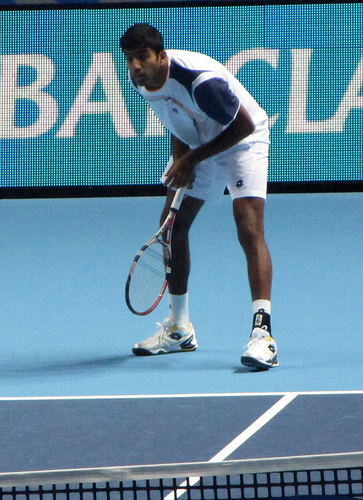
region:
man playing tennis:
[115, 19, 281, 373]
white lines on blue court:
[2, 387, 362, 499]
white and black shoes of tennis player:
[129, 325, 278, 368]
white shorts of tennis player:
[159, 152, 268, 196]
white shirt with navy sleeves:
[135, 53, 269, 150]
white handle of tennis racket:
[165, 179, 190, 207]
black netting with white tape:
[1, 452, 360, 499]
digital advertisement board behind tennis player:
[3, 7, 362, 184]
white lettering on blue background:
[4, 40, 361, 158]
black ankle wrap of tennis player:
[253, 308, 273, 330]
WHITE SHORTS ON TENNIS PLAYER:
[177, 122, 278, 208]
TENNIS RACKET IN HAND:
[129, 231, 172, 332]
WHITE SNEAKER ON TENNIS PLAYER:
[230, 322, 297, 387]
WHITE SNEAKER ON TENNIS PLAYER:
[132, 338, 199, 368]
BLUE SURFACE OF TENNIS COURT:
[19, 356, 285, 483]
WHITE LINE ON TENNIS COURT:
[195, 385, 295, 476]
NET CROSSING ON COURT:
[53, 432, 335, 499]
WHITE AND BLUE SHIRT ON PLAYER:
[154, 58, 251, 161]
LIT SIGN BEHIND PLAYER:
[26, 34, 354, 201]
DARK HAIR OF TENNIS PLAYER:
[120, 14, 183, 55]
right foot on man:
[125, 316, 213, 355]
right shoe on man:
[100, 295, 215, 373]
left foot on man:
[230, 296, 281, 388]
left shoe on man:
[219, 316, 300, 400]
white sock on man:
[151, 270, 202, 333]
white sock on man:
[240, 298, 290, 339]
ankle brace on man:
[230, 308, 289, 344]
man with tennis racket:
[151, 163, 209, 319]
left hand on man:
[143, 144, 196, 183]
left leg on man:
[229, 171, 280, 292]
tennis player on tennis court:
[104, 21, 290, 371]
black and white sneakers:
[118, 319, 287, 373]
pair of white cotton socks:
[161, 287, 275, 330]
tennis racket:
[120, 172, 192, 320]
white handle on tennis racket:
[169, 180, 189, 216]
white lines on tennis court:
[1, 387, 361, 496]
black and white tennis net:
[1, 448, 361, 498]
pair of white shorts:
[157, 114, 273, 202]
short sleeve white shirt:
[126, 46, 275, 155]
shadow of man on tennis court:
[2, 339, 258, 392]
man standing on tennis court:
[95, 15, 295, 375]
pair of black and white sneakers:
[119, 318, 285, 377]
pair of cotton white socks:
[164, 288, 271, 333]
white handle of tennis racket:
[170, 183, 187, 215]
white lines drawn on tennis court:
[3, 391, 356, 456]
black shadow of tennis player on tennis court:
[2, 344, 268, 386]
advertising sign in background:
[2, 40, 360, 150]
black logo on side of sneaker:
[163, 328, 191, 344]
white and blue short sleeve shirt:
[117, 53, 281, 153]